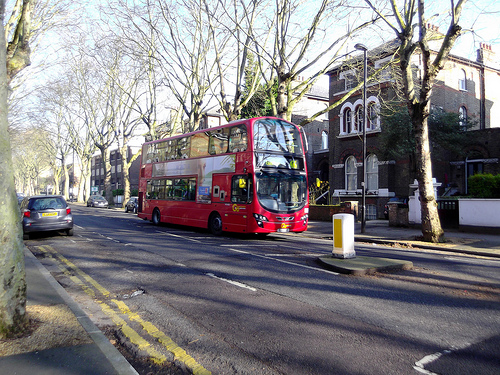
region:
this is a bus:
[112, 97, 342, 271]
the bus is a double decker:
[109, 88, 336, 274]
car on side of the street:
[15, 169, 107, 300]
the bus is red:
[106, 66, 324, 271]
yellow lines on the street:
[49, 229, 207, 373]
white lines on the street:
[109, 208, 311, 337]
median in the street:
[308, 193, 405, 336]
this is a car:
[21, 186, 83, 251]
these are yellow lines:
[111, 301, 188, 373]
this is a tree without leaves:
[367, 11, 469, 249]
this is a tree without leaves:
[251, 0, 378, 152]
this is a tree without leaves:
[154, 0, 254, 140]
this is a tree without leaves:
[82, 12, 184, 134]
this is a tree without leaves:
[42, 73, 146, 200]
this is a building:
[321, 8, 489, 242]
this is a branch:
[280, 13, 404, 75]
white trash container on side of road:
[325, 205, 355, 258]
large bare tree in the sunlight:
[360, 0, 482, 240]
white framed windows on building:
[335, 90, 385, 130]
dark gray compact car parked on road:
[11, 190, 81, 245]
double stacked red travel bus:
[131, 112, 311, 242]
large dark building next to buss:
[321, 40, 496, 230]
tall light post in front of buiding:
[350, 32, 375, 227]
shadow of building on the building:
[410, 60, 495, 130]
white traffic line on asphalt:
[200, 255, 265, 297]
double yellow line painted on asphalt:
[26, 233, 221, 373]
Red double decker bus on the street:
[132, 115, 310, 238]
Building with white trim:
[326, 25, 499, 225]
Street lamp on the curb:
[352, 41, 374, 236]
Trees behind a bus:
[135, 6, 320, 158]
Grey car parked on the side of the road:
[18, 192, 74, 241]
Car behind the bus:
[122, 188, 152, 221]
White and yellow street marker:
[330, 210, 358, 264]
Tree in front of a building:
[396, 3, 466, 245]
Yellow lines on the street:
[35, 243, 213, 374]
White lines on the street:
[73, 213, 345, 293]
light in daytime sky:
[4, 1, 497, 195]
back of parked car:
[24, 197, 71, 235]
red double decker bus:
[138, 116, 308, 236]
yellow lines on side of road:
[0, 244, 205, 372]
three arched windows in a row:
[339, 96, 382, 138]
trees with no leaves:
[7, 1, 499, 193]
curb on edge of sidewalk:
[0, 246, 137, 373]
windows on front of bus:
[254, 119, 306, 211]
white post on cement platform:
[317, 212, 413, 276]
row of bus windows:
[142, 125, 247, 165]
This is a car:
[11, 180, 96, 255]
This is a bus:
[128, 111, 323, 256]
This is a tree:
[3, 2, 43, 361]